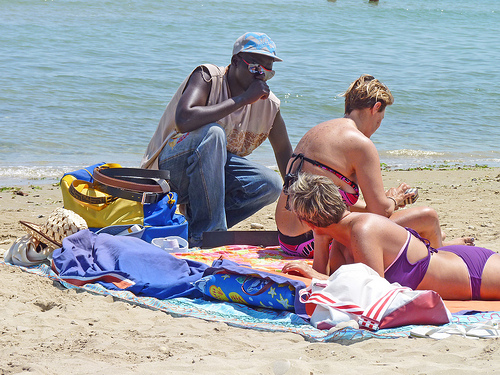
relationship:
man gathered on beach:
[142, 32, 290, 260] [3, 151, 499, 374]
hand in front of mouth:
[243, 74, 271, 103] [251, 76, 272, 92]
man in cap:
[142, 32, 290, 260] [230, 29, 283, 61]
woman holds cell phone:
[275, 72, 441, 256] [397, 176, 418, 207]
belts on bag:
[69, 166, 163, 210] [61, 161, 191, 241]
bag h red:
[298, 263, 454, 327] [401, 294, 449, 323]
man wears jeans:
[142, 32, 290, 260] [158, 135, 282, 244]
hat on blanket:
[15, 206, 86, 250] [8, 233, 52, 277]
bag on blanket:
[298, 263, 454, 327] [90, 273, 493, 343]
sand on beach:
[5, 270, 499, 373] [3, 151, 499, 374]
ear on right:
[372, 93, 384, 116] [348, 74, 444, 238]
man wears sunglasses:
[142, 32, 290, 260] [226, 48, 277, 80]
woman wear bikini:
[290, 171, 499, 303] [384, 228, 495, 297]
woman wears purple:
[290, 171, 499, 303] [392, 263, 419, 283]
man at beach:
[142, 32, 290, 260] [3, 151, 499, 374]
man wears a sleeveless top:
[142, 32, 290, 260] [140, 61, 285, 175]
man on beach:
[142, 32, 290, 260] [3, 151, 499, 374]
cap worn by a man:
[230, 29, 283, 61] [142, 32, 290, 260]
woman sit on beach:
[290, 171, 499, 303] [3, 151, 499, 374]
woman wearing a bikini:
[290, 171, 499, 303] [384, 228, 495, 297]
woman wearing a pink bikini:
[275, 72, 441, 256] [278, 153, 360, 263]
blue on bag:
[150, 211, 175, 235] [61, 161, 191, 241]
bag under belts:
[61, 161, 191, 241] [69, 166, 163, 210]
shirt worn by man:
[140, 61, 285, 175] [142, 32, 290, 260]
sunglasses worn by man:
[226, 48, 277, 80] [142, 32, 290, 260]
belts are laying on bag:
[69, 166, 163, 210] [61, 161, 191, 241]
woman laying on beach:
[290, 171, 499, 303] [3, 151, 499, 374]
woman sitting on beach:
[275, 72, 441, 256] [3, 151, 499, 374]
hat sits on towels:
[15, 206, 86, 250] [8, 233, 52, 277]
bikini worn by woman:
[384, 228, 495, 297] [290, 171, 499, 303]